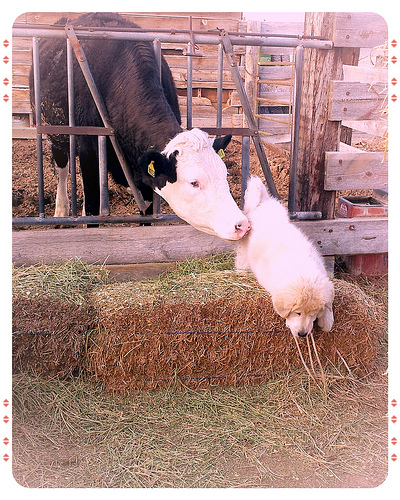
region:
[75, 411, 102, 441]
hay stick grain on a field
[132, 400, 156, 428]
hay stick grain on a field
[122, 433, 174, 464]
hay stick grain on a field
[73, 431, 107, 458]
hay stick grain on a field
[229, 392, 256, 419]
hay stick grain on a field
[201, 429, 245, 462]
hay stick grain on a field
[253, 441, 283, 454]
hay stick grain on a field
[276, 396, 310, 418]
hay stick grain on a field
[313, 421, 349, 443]
hay stick grain on a field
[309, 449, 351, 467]
hay stick grain on a field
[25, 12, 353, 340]
bull and puppy keeping each other company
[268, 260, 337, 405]
puppy playing with a rope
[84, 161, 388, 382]
puppy standing on a bale of hay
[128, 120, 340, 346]
bull curious about puppy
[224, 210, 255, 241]
bull has a ring through its nose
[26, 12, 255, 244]
bull is mostly black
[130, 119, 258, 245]
bull has a white head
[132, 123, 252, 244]
bull has black ears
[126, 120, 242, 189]
bull wearing tags in each ear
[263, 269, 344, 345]
puppy has floppy ears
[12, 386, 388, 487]
an area of dirt ground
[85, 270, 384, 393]
a hay bale on the ground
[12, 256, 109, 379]
a hay bale on the ground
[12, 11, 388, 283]
a wooden fence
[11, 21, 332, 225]
a metal gate on the fence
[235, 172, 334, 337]
a white dog on a hay bale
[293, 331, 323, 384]
rope in the dog's mouth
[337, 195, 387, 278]
a red metal container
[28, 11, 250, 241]
a cow inside the gate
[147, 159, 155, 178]
an ear tag on the cow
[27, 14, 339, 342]
cow nuzzling puppy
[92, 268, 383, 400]
bale of hay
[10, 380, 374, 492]
green straw and grass on ground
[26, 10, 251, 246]
cow in metal fence enclosure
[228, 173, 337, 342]
puppy standing in front of metal pen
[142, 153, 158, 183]
yellow tag in cow's ear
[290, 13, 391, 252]
wooden fence next to cow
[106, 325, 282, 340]
line of rope around bale of hay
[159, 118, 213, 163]
white tuft of hair on top of cow's head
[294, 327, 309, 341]
black nose of dog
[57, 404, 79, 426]
hay stick on a field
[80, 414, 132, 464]
hay stick on a field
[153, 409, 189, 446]
hay stick on a field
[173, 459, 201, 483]
hay stick on a field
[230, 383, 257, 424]
hay stick on a field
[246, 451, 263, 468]
hay stick on a field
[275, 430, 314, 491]
hay stick on a field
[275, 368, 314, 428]
hay stick on a field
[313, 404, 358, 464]
hay stick on a field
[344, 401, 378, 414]
hay stick on a field